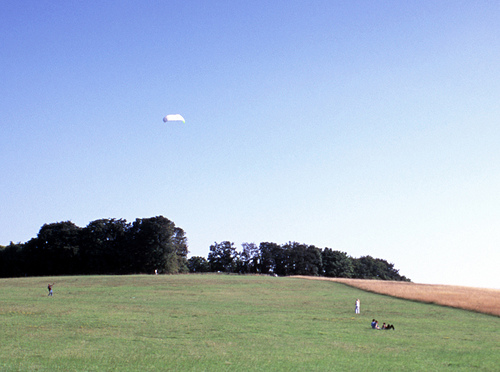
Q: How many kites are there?
A: One.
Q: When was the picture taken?
A: Daytime.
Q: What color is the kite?
A: White.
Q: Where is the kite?
A: In the sky.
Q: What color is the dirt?
A: Brown.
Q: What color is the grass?
A: Green.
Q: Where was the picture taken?
A: A field.